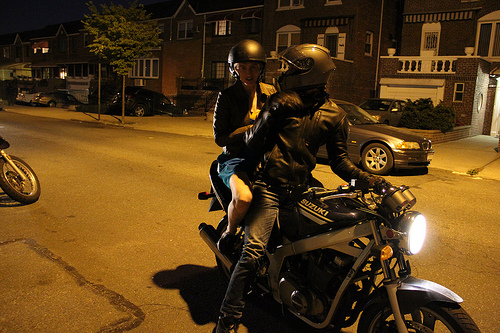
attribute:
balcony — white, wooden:
[397, 55, 455, 76]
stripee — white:
[406, 9, 474, 31]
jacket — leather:
[230, 63, 376, 215]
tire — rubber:
[0, 149, 45, 208]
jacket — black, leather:
[233, 88, 380, 191]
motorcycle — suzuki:
[188, 138, 485, 332]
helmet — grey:
[283, 40, 337, 102]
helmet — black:
[224, 39, 270, 68]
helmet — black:
[221, 34, 276, 86]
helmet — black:
[276, 42, 335, 94]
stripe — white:
[400, 10, 416, 22]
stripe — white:
[402, 12, 473, 21]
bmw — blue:
[239, 80, 422, 172]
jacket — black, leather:
[234, 92, 385, 205]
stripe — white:
[443, 11, 452, 21]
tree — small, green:
[79, 4, 211, 134]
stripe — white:
[463, 9, 473, 21]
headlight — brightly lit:
[392, 208, 428, 258]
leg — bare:
[220, 166, 253, 238]